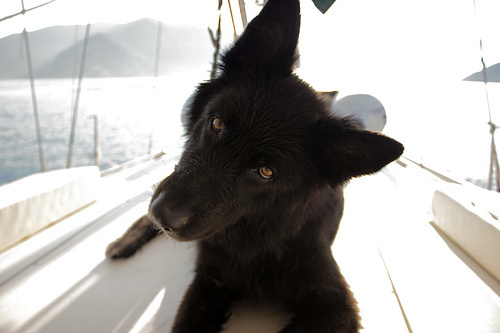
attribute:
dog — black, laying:
[149, 41, 365, 302]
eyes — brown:
[206, 110, 286, 191]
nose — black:
[149, 185, 197, 230]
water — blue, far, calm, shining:
[18, 76, 90, 139]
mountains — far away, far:
[46, 19, 116, 70]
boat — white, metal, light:
[29, 188, 107, 329]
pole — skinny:
[80, 31, 94, 58]